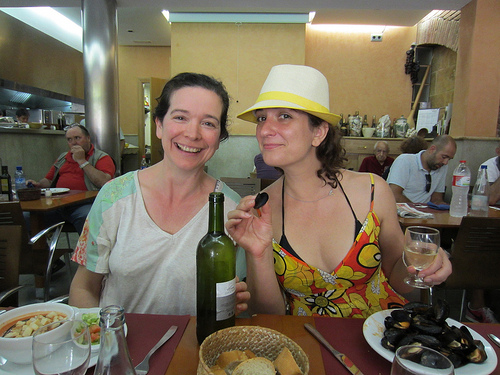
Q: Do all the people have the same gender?
A: No, they are both male and female.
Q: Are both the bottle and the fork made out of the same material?
A: No, the bottle is made of glass and the fork is made of metal.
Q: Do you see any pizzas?
A: No, there are no pizzas.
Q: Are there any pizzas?
A: No, there are no pizzas.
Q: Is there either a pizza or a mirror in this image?
A: No, there are no pizzas or mirrors.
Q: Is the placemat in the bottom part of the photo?
A: Yes, the placemat is in the bottom of the image.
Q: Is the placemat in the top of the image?
A: No, the placemat is in the bottom of the image.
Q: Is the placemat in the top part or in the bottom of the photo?
A: The placemat is in the bottom of the image.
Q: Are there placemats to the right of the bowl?
A: Yes, there is a placemat to the right of the bowl.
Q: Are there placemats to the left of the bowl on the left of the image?
A: No, the placemat is to the right of the bowl.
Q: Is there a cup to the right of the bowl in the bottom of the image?
A: No, there is a placemat to the right of the bowl.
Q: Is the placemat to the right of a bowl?
A: Yes, the placemat is to the right of a bowl.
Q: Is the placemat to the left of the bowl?
A: No, the placemat is to the right of the bowl.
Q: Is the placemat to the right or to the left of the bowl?
A: The placemat is to the right of the bowl.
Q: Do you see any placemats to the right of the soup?
A: Yes, there is a placemat to the right of the soup.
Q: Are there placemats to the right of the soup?
A: Yes, there is a placemat to the right of the soup.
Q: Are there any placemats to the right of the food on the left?
A: Yes, there is a placemat to the right of the soup.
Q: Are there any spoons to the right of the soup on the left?
A: No, there is a placemat to the right of the soup.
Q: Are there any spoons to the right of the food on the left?
A: No, there is a placemat to the right of the soup.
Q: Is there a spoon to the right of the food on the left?
A: No, there is a placemat to the right of the soup.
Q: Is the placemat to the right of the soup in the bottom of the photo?
A: Yes, the placemat is to the right of the soup.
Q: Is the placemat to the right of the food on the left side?
A: Yes, the placemat is to the right of the soup.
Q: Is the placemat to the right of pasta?
A: No, the placemat is to the right of the soup.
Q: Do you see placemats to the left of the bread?
A: Yes, there is a placemat to the left of the bread.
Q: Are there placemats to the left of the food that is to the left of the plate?
A: Yes, there is a placemat to the left of the bread.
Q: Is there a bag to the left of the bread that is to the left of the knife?
A: No, there is a placemat to the left of the bread.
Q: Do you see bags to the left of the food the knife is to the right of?
A: No, there is a placemat to the left of the bread.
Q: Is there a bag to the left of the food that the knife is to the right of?
A: No, there is a placemat to the left of the bread.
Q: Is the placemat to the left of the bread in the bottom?
A: Yes, the placemat is to the left of the bread.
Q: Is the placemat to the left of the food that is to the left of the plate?
A: Yes, the placemat is to the left of the bread.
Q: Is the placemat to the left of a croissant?
A: No, the placemat is to the left of the bread.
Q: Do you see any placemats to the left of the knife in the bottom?
A: Yes, there is a placemat to the left of the knife.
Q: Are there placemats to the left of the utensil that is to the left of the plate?
A: Yes, there is a placemat to the left of the knife.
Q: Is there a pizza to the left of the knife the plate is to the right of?
A: No, there is a placemat to the left of the knife.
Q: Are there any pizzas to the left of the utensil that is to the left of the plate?
A: No, there is a placemat to the left of the knife.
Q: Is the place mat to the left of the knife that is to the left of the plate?
A: Yes, the place mat is to the left of the knife.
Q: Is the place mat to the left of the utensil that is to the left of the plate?
A: Yes, the place mat is to the left of the knife.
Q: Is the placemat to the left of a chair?
A: No, the placemat is to the left of the knife.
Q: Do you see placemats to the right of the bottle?
A: Yes, there is a placemat to the right of the bottle.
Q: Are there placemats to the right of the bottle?
A: Yes, there is a placemat to the right of the bottle.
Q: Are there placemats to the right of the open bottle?
A: Yes, there is a placemat to the right of the bottle.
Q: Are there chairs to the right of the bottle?
A: No, there is a placemat to the right of the bottle.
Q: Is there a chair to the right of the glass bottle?
A: No, there is a placemat to the right of the bottle.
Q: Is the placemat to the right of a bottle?
A: Yes, the placemat is to the right of a bottle.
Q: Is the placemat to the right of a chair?
A: No, the placemat is to the right of a bottle.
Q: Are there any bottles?
A: Yes, there is a bottle.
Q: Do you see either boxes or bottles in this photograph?
A: Yes, there is a bottle.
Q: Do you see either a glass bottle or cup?
A: Yes, there is a glass bottle.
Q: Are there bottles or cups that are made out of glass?
A: Yes, the bottle is made of glass.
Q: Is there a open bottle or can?
A: Yes, there is an open bottle.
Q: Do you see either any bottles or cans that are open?
A: Yes, the bottle is open.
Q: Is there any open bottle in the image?
A: Yes, there is an open bottle.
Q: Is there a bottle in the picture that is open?
A: Yes, there is a bottle that is open.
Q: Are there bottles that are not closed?
A: Yes, there is a open bottle.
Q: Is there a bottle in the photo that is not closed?
A: Yes, there is a open bottle.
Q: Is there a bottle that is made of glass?
A: Yes, there is a bottle that is made of glass.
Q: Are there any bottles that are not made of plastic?
A: Yes, there is a bottle that is made of glass.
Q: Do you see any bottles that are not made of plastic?
A: Yes, there is a bottle that is made of glass.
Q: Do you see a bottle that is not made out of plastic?
A: Yes, there is a bottle that is made of glass.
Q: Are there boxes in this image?
A: No, there are no boxes.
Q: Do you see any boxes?
A: No, there are no boxes.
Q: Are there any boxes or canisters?
A: No, there are no boxes or canisters.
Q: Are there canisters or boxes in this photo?
A: No, there are no boxes or canisters.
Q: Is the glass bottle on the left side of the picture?
A: Yes, the bottle is on the left of the image.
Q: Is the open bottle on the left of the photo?
A: Yes, the bottle is on the left of the image.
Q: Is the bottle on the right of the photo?
A: No, the bottle is on the left of the image.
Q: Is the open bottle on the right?
A: No, the bottle is on the left of the image.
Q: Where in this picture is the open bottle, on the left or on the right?
A: The bottle is on the left of the image.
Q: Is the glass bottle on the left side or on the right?
A: The bottle is on the left of the image.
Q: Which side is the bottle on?
A: The bottle is on the left of the image.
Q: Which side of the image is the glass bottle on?
A: The bottle is on the left of the image.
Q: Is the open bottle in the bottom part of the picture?
A: Yes, the bottle is in the bottom of the image.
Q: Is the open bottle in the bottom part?
A: Yes, the bottle is in the bottom of the image.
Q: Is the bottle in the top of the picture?
A: No, the bottle is in the bottom of the image.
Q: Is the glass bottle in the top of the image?
A: No, the bottle is in the bottom of the image.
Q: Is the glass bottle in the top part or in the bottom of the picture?
A: The bottle is in the bottom of the image.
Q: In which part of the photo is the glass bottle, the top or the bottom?
A: The bottle is in the bottom of the image.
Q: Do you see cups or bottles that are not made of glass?
A: No, there is a bottle but it is made of glass.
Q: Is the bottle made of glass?
A: Yes, the bottle is made of glass.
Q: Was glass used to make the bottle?
A: Yes, the bottle is made of glass.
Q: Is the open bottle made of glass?
A: Yes, the bottle is made of glass.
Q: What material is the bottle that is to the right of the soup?
A: The bottle is made of glass.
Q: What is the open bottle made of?
A: The bottle is made of glass.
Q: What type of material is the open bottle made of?
A: The bottle is made of glass.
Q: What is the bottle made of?
A: The bottle is made of glass.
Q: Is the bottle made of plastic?
A: No, the bottle is made of glass.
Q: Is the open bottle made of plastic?
A: No, the bottle is made of glass.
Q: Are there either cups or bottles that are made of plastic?
A: No, there is a bottle but it is made of glass.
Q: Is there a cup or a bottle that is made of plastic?
A: No, there is a bottle but it is made of glass.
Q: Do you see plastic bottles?
A: No, there is a bottle but it is made of glass.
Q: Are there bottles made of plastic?
A: No, there is a bottle but it is made of glass.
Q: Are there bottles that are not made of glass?
A: No, there is a bottle but it is made of glass.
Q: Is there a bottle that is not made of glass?
A: No, there is a bottle but it is made of glass.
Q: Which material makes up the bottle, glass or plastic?
A: The bottle is made of glass.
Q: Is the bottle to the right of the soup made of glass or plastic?
A: The bottle is made of glass.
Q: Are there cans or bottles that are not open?
A: No, there is a bottle but it is open.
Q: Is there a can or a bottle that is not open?
A: No, there is a bottle but it is open.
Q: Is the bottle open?
A: Yes, the bottle is open.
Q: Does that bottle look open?
A: Yes, the bottle is open.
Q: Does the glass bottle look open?
A: Yes, the bottle is open.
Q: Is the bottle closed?
A: No, the bottle is open.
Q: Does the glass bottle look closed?
A: No, the bottle is open.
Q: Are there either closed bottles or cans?
A: No, there is a bottle but it is open.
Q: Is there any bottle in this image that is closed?
A: No, there is a bottle but it is open.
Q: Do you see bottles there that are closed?
A: No, there is a bottle but it is open.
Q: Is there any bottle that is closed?
A: No, there is a bottle but it is open.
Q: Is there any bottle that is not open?
A: No, there is a bottle but it is open.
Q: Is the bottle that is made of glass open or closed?
A: The bottle is open.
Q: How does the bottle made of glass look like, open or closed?
A: The bottle is open.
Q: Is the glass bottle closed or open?
A: The bottle is open.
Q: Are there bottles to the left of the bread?
A: Yes, there is a bottle to the left of the bread.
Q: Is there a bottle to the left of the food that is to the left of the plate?
A: Yes, there is a bottle to the left of the bread.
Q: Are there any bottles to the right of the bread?
A: No, the bottle is to the left of the bread.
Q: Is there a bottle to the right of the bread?
A: No, the bottle is to the left of the bread.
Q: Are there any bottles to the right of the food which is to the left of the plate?
A: No, the bottle is to the left of the bread.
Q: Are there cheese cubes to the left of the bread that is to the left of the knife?
A: No, there is a bottle to the left of the bread.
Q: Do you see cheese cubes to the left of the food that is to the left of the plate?
A: No, there is a bottle to the left of the bread.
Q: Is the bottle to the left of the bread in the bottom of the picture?
A: Yes, the bottle is to the left of the bread.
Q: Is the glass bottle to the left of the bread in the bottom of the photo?
A: Yes, the bottle is to the left of the bread.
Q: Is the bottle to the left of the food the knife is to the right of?
A: Yes, the bottle is to the left of the bread.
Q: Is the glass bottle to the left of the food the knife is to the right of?
A: Yes, the bottle is to the left of the bread.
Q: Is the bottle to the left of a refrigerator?
A: No, the bottle is to the left of the bread.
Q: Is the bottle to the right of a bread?
A: No, the bottle is to the left of a bread.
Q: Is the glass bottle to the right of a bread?
A: No, the bottle is to the left of a bread.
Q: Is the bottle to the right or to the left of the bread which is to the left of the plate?
A: The bottle is to the left of the bread.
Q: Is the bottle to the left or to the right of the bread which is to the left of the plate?
A: The bottle is to the left of the bread.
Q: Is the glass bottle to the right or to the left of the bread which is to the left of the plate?
A: The bottle is to the left of the bread.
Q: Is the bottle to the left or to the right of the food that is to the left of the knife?
A: The bottle is to the left of the bread.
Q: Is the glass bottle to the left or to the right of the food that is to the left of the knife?
A: The bottle is to the left of the bread.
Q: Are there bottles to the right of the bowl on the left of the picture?
A: Yes, there is a bottle to the right of the bowl.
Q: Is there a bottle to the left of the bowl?
A: No, the bottle is to the right of the bowl.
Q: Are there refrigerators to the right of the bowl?
A: No, there is a bottle to the right of the bowl.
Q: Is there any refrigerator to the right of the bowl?
A: No, there is a bottle to the right of the bowl.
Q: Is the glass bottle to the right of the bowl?
A: Yes, the bottle is to the right of the bowl.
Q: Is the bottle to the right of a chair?
A: No, the bottle is to the right of the bowl.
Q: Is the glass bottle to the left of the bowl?
A: No, the bottle is to the right of the bowl.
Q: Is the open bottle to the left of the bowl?
A: No, the bottle is to the right of the bowl.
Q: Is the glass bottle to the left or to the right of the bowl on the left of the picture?
A: The bottle is to the right of the bowl.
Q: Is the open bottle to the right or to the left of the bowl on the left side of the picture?
A: The bottle is to the right of the bowl.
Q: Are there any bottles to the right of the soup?
A: Yes, there is a bottle to the right of the soup.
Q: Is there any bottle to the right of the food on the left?
A: Yes, there is a bottle to the right of the soup.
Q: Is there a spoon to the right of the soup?
A: No, there is a bottle to the right of the soup.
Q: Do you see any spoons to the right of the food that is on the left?
A: No, there is a bottle to the right of the soup.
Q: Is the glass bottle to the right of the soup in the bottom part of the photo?
A: Yes, the bottle is to the right of the soup.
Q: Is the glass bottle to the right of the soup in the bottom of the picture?
A: Yes, the bottle is to the right of the soup.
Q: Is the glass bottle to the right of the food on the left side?
A: Yes, the bottle is to the right of the soup.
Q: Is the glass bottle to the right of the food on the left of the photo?
A: Yes, the bottle is to the right of the soup.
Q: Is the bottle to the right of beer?
A: No, the bottle is to the right of the soup.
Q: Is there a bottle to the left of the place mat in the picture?
A: Yes, there is a bottle to the left of the place mat.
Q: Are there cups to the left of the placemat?
A: No, there is a bottle to the left of the placemat.